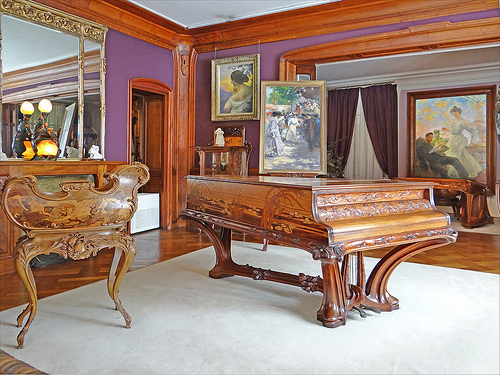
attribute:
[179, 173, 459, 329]
piano — antique, ornate, old, ornately carved, musical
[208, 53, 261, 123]
painting — framed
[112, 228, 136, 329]
leg — curved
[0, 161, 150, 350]
furniture — antique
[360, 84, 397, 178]
drape — purple, burgundy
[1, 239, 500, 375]
rug — white, large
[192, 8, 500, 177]
wall — purple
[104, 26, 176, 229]
wall — purple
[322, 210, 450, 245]
cover — closed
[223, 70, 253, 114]
woman — painted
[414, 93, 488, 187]
painting — framed, colorful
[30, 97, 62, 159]
lamp — lit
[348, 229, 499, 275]
floor — wood, brown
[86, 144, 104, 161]
statue — white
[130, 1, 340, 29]
ceiling — white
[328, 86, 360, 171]
drape — purple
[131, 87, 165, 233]
doorway — framed